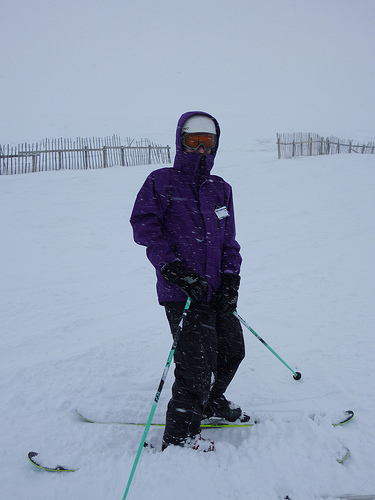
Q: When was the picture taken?
A: Daytime.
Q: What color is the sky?
A: White.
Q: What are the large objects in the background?
A: Fences.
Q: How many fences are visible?
A: Two.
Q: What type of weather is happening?
A: Snow.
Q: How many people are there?
A: One.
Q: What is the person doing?
A: Skiing.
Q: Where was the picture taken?
A: On the ski slopes.